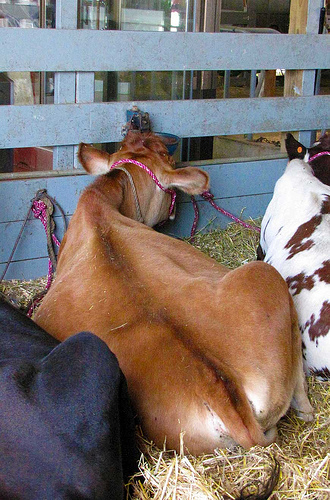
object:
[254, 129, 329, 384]
cow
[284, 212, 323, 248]
spot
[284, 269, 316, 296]
spot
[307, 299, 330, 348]
spot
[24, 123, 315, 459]
cow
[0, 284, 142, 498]
cow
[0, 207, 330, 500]
straw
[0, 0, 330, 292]
fence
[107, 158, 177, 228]
rope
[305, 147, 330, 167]
rope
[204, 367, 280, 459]
tail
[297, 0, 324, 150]
post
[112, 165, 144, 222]
rope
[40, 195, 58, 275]
rope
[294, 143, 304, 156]
tag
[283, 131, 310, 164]
ear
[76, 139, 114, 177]
left ear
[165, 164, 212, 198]
right ear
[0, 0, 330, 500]
pen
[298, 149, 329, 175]
neck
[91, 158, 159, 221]
neck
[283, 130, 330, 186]
head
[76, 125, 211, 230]
head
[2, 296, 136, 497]
fur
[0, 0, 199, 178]
window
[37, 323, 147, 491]
hind quarter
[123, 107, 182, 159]
bowl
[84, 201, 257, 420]
stripe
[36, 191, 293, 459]
back